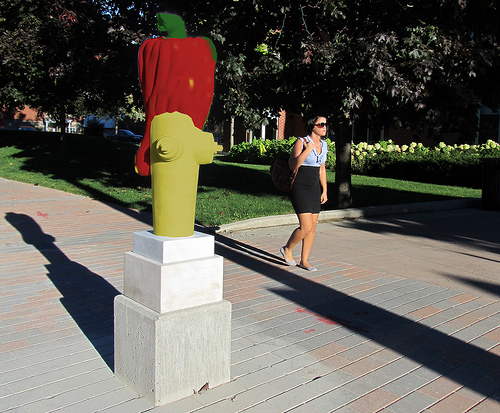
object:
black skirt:
[289, 165, 322, 214]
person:
[270, 115, 329, 273]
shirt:
[298, 134, 329, 167]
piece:
[156, 13, 218, 63]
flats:
[279, 246, 317, 272]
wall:
[351, 139, 500, 185]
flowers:
[350, 138, 499, 160]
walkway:
[0, 176, 500, 413]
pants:
[288, 165, 322, 215]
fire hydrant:
[133, 11, 223, 237]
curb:
[214, 198, 470, 234]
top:
[298, 135, 328, 167]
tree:
[213, 0, 500, 209]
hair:
[306, 115, 328, 137]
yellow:
[159, 168, 189, 203]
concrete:
[169, 275, 211, 303]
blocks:
[157, 242, 217, 382]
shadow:
[63, 180, 287, 267]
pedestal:
[113, 229, 232, 408]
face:
[313, 117, 327, 136]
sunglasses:
[314, 122, 327, 128]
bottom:
[149, 111, 224, 237]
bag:
[270, 137, 308, 192]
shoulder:
[298, 135, 311, 144]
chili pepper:
[133, 12, 217, 177]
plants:
[225, 135, 500, 188]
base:
[112, 227, 232, 406]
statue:
[133, 12, 223, 238]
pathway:
[0, 179, 500, 413]